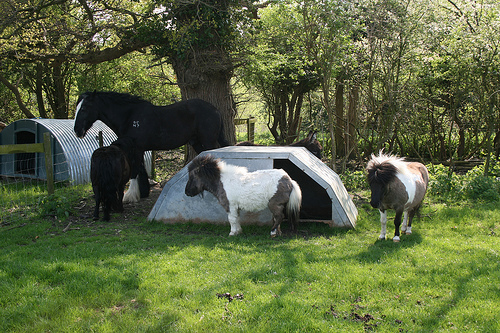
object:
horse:
[183, 151, 301, 240]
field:
[0, 0, 500, 332]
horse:
[364, 148, 430, 243]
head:
[185, 153, 216, 197]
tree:
[59, 8, 254, 178]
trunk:
[171, 21, 237, 168]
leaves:
[160, 25, 166, 31]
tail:
[285, 179, 303, 224]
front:
[11, 125, 57, 185]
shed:
[4, 115, 159, 195]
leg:
[267, 199, 283, 237]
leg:
[226, 207, 239, 236]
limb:
[35, 38, 150, 68]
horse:
[71, 89, 229, 198]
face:
[73, 92, 103, 140]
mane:
[185, 155, 250, 180]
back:
[267, 172, 290, 206]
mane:
[90, 90, 145, 103]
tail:
[218, 117, 229, 147]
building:
[145, 146, 361, 232]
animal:
[89, 139, 139, 222]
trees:
[242, 10, 490, 158]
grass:
[0, 189, 500, 333]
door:
[270, 159, 336, 225]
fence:
[237, 114, 260, 140]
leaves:
[290, 55, 293, 56]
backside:
[222, 164, 292, 181]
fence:
[0, 133, 96, 217]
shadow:
[336, 235, 428, 264]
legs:
[394, 210, 401, 242]